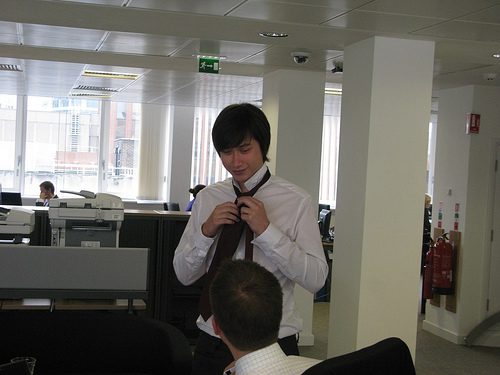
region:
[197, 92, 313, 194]
head of a person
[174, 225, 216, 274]
arm of a person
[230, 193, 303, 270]
arm of a person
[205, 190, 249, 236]
hand of a person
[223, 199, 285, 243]
hand of a person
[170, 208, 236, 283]
an arm of a person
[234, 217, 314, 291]
an arm of a person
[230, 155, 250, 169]
nose of a person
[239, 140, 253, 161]
an eye of a person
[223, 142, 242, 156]
an eye of a person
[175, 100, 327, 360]
a young man putting tie on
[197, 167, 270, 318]
an untied black necktie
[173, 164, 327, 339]
a white long sleeve shirt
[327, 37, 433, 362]
a tall white structural column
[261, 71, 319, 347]
a tall white structural column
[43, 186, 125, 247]
a large copy machine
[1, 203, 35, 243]
a large copy machine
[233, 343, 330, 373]
a white striped dress shirt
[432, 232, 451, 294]
a red fire extinguisher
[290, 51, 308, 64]
an overhead security camera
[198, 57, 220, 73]
a green directional sign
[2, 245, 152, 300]
a grey desk partition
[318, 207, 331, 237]
a black computer monitor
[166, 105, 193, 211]
a white structural beam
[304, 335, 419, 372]
a black computer chair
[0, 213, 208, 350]
a grey computer partition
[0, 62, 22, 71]
a metal ceiling vent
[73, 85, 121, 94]
a metal ceiling vent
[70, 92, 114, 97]
a metal ceiling vent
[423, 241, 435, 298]
a red fire extinguisher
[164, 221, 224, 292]
arm of a person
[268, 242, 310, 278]
arm of a person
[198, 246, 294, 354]
head of a person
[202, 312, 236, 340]
ear of a person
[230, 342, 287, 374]
neck of a person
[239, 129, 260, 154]
an eye of a person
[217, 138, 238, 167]
an eye of a person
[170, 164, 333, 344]
Man wearing a shirt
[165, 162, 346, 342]
Man is wearing a shirt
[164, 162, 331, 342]
Man wearing a white shirt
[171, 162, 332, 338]
Man is wearing a white shirt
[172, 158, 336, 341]
Man wearing a dress shirt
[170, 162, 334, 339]
Man is wearing a dress shirt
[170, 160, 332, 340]
Man wearing a white dress shirt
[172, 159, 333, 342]
Man is wearing a white dress shirt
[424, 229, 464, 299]
Fire hydrant is on the wall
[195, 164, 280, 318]
Man is putting on a tie